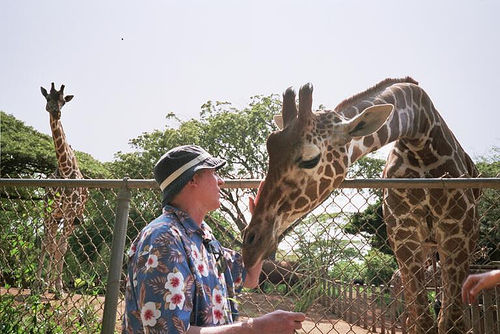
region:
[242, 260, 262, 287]
the tongue of a giraffe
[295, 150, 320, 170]
the eye of a giraffe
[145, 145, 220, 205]
a man's black and white hat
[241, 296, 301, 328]
the hand of a man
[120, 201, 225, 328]
a man's flower shirt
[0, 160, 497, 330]
part of a chain link fence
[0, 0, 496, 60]
part of a clear sky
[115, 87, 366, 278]
part of a large tree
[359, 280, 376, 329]
a long pole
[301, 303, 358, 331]
an area of sand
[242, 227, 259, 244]
giraffe's nose holes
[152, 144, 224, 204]
blue and white bucket hat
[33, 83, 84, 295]
giraffe behind the fence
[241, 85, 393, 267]
giraffe's head in front of fence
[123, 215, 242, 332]
Floral pattern on the man's shirt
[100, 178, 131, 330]
metal fence post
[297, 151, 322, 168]
giraffe's eye is black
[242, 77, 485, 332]
giraffe has spots on it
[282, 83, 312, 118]
two horns on the giraffe's head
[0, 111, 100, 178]
tree canopy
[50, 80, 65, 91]
The horns on the giraffe's head on the left.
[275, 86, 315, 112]
The horns on the giraffe's head on the right.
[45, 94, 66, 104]
The eyes of the giraffe on the left.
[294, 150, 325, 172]
The eye of the giraffe on the right.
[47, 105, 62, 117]
The nose of the giraffe on the left.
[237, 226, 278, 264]
The nose of the giraffe on the right.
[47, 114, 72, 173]
The neck of the giraffe on the left.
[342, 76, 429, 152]
The neck of the giraffe on the right.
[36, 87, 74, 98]
The ears of the giraffe on the left.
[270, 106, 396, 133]
The ears of the giraffe on the right.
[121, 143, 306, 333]
the man petting the giraffe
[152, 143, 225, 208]
the hat on the man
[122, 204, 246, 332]
the floral shirt on the man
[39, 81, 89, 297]
the giraffe standing in the enclosure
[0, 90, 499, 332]
the trees behind the fence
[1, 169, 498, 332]
the chain link fence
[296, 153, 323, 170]
the eye on the giraffe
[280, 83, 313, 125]
the horns on the giraffe's head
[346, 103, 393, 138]
the ear on the giraffe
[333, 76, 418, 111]
the mane on the giraffe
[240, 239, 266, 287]
Tongue sticking out of giraffe's mouth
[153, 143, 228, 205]
Blue and white hat on man's head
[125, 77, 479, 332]
Man in blue hawaiian shirt petting giraffe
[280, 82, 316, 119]
Two horns on top of giraffe's head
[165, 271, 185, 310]
White flowers with red centers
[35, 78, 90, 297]
Giraffe walking behind fence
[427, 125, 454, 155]
Brown spot on giraffe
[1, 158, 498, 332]
Grey chain link fence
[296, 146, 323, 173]
Giraffe's eye with eyelashes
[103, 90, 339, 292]
Tall green tree in background